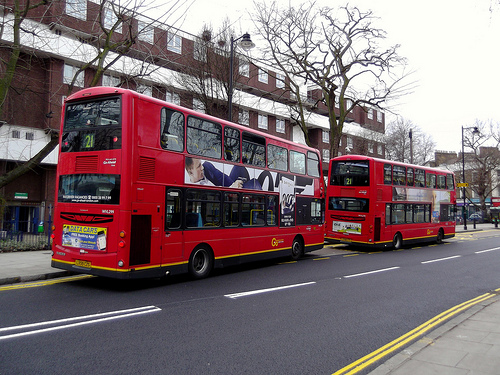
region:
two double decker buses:
[41, 68, 499, 278]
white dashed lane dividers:
[197, 243, 474, 294]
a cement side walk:
[365, 270, 497, 374]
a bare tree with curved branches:
[247, 1, 409, 143]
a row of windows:
[97, 3, 211, 60]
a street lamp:
[222, 28, 262, 118]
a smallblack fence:
[6, 225, 48, 250]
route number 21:
[72, 126, 111, 160]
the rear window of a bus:
[55, 90, 122, 135]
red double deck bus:
[82, 95, 330, 283]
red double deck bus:
[342, 152, 464, 247]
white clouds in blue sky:
[398, 45, 459, 86]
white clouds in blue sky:
[438, 45, 498, 92]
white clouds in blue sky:
[407, 18, 472, 86]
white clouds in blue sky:
[434, 32, 482, 104]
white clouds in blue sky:
[407, 45, 477, 122]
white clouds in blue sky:
[414, 12, 464, 63]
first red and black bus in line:
[59, 83, 334, 265]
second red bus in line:
[339, 137, 462, 251]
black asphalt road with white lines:
[67, 278, 445, 373]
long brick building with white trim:
[64, 15, 388, 163]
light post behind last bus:
[455, 122, 484, 224]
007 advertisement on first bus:
[182, 152, 334, 215]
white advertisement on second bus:
[392, 185, 454, 210]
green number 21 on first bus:
[72, 128, 105, 158]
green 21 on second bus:
[338, 171, 357, 185]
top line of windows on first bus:
[164, 100, 329, 179]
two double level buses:
[27, 78, 477, 323]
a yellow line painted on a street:
[386, 294, 485, 373]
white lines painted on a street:
[185, 252, 470, 335]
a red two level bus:
[55, 77, 337, 311]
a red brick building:
[0, 17, 297, 88]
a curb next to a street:
[1, 262, 47, 307]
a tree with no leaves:
[462, 129, 496, 232]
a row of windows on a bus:
[132, 117, 317, 168]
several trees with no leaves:
[49, 18, 400, 93]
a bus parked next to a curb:
[0, 101, 338, 300]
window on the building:
[258, 68, 271, 85]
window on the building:
[188, 41, 213, 62]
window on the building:
[135, 21, 153, 43]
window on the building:
[278, 119, 293, 136]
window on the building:
[258, 117, 268, 127]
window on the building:
[236, 108, 253, 124]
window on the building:
[188, 95, 208, 113]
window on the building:
[60, 68, 92, 85]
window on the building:
[321, 130, 336, 145]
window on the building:
[276, 72, 290, 91]